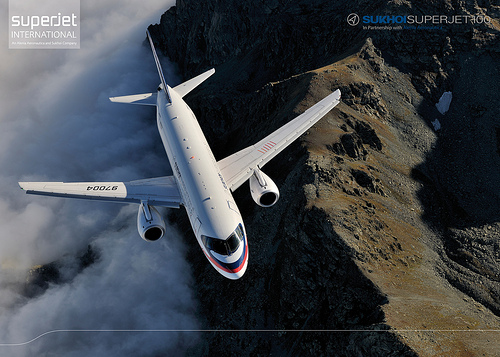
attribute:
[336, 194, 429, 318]
dirt — brown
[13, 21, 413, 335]
plane — white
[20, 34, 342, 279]
plane — flying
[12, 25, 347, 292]
plane — white, soaring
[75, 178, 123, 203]
numbers — black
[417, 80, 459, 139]
stones — white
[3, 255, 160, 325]
clouds — fluffy, white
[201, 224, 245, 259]
windshield — black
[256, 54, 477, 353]
mountain — brown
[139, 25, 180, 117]
tail fin — white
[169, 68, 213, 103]
tail fin — white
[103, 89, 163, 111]
tail fin — white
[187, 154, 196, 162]
light — red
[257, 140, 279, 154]
stripes — red